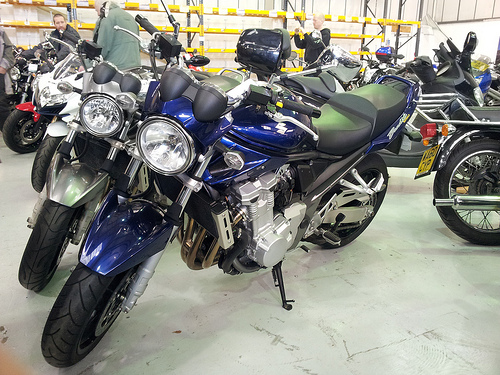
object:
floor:
[0, 131, 500, 374]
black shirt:
[293, 28, 331, 63]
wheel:
[432, 142, 500, 247]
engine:
[213, 175, 327, 276]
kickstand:
[270, 260, 294, 311]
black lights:
[191, 82, 228, 122]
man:
[23, 12, 85, 61]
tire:
[433, 142, 500, 246]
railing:
[0, 0, 419, 28]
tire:
[39, 260, 144, 367]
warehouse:
[0, 0, 499, 374]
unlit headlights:
[133, 116, 195, 177]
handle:
[283, 100, 321, 119]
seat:
[310, 102, 373, 156]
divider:
[329, 90, 376, 139]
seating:
[326, 83, 408, 143]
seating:
[305, 103, 375, 157]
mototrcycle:
[415, 98, 500, 246]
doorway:
[436, 17, 500, 64]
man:
[290, 13, 332, 63]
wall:
[0, 0, 422, 68]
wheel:
[41, 263, 142, 367]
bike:
[41, 13, 422, 368]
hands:
[292, 27, 302, 35]